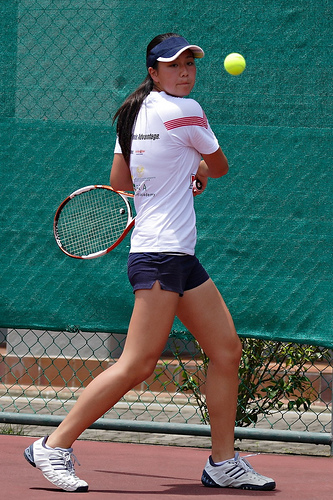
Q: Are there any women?
A: Yes, there is a woman.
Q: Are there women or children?
A: Yes, there is a woman.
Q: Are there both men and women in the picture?
A: No, there is a woman but no men.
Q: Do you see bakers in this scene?
A: No, there are no bakers.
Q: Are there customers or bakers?
A: No, there are no bakers or customers.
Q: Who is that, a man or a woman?
A: That is a woman.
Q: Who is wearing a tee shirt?
A: The woman is wearing a tee shirt.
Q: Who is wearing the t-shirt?
A: The woman is wearing a tee shirt.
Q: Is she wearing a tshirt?
A: Yes, the woman is wearing a tshirt.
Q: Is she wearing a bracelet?
A: No, the woman is wearing a tshirt.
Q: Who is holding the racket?
A: The woman is holding the racket.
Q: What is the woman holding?
A: The woman is holding the racket.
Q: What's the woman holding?
A: The woman is holding the racket.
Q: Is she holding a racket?
A: Yes, the woman is holding a racket.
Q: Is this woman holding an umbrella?
A: No, the woman is holding a racket.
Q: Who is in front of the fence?
A: The woman is in front of the fence.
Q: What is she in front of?
A: The woman is in front of the fence.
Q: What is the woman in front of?
A: The woman is in front of the fence.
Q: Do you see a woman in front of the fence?
A: Yes, there is a woman in front of the fence.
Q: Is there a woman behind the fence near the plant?
A: No, the woman is in front of the fence.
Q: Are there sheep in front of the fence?
A: No, there is a woman in front of the fence.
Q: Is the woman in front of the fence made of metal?
A: Yes, the woman is in front of the fence.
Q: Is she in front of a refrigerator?
A: No, the woman is in front of the fence.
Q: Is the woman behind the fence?
A: No, the woman is in front of the fence.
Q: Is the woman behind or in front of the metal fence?
A: The woman is in front of the fence.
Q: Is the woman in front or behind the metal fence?
A: The woman is in front of the fence.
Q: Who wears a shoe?
A: The woman wears a shoe.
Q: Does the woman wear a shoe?
A: Yes, the woman wears a shoe.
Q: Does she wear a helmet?
A: No, the woman wears a shoe.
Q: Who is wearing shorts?
A: The woman is wearing shorts.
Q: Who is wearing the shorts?
A: The woman is wearing shorts.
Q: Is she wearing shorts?
A: Yes, the woman is wearing shorts.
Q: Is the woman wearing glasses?
A: No, the woman is wearing shorts.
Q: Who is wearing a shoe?
A: The woman is wearing a shoe.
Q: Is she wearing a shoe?
A: Yes, the woman is wearing a shoe.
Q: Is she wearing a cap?
A: No, the woman is wearing a shoe.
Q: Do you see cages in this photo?
A: No, there are no cages.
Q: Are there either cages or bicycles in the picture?
A: No, there are no cages or bicycles.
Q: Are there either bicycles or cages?
A: No, there are no cages or bicycles.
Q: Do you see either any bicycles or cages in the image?
A: No, there are no cages or bicycles.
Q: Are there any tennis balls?
A: Yes, there is a tennis ball.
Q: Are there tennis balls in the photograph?
A: Yes, there is a tennis ball.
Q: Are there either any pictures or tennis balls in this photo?
A: Yes, there is a tennis ball.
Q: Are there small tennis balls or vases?
A: Yes, there is a small tennis ball.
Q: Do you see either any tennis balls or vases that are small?
A: Yes, the tennis ball is small.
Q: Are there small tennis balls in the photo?
A: Yes, there is a small tennis ball.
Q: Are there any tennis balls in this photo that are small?
A: Yes, there is a tennis ball that is small.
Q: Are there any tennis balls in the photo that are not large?
A: Yes, there is a small tennis ball.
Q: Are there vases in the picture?
A: No, there are no vases.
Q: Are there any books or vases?
A: No, there are no vases or books.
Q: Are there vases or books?
A: No, there are no vases or books.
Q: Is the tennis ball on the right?
A: Yes, the tennis ball is on the right of the image.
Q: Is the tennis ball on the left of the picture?
A: No, the tennis ball is on the right of the image.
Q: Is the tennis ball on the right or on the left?
A: The tennis ball is on the right of the image.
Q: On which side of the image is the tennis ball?
A: The tennis ball is on the right of the image.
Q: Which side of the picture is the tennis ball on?
A: The tennis ball is on the right of the image.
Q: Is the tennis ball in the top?
A: Yes, the tennis ball is in the top of the image.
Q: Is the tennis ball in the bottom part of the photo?
A: No, the tennis ball is in the top of the image.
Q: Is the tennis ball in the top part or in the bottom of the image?
A: The tennis ball is in the top of the image.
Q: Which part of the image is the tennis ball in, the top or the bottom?
A: The tennis ball is in the top of the image.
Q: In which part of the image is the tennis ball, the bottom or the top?
A: The tennis ball is in the top of the image.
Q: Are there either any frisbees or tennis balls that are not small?
A: No, there is a tennis ball but it is small.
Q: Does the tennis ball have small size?
A: Yes, the tennis ball is small.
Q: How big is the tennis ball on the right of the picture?
A: The tennis ball is small.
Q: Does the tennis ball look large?
A: No, the tennis ball is small.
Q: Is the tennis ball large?
A: No, the tennis ball is small.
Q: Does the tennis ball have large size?
A: No, the tennis ball is small.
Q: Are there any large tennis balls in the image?
A: No, there is a tennis ball but it is small.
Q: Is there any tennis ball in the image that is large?
A: No, there is a tennis ball but it is small.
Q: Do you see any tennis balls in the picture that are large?
A: No, there is a tennis ball but it is small.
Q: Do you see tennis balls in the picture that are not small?
A: No, there is a tennis ball but it is small.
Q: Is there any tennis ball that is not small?
A: No, there is a tennis ball but it is small.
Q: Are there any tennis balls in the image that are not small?
A: No, there is a tennis ball but it is small.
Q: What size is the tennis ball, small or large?
A: The tennis ball is small.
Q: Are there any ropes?
A: No, there are no ropes.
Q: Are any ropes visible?
A: No, there are no ropes.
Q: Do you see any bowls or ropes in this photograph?
A: No, there are no ropes or bowls.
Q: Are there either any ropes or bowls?
A: No, there are no ropes or bowls.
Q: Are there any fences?
A: Yes, there is a fence.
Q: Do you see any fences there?
A: Yes, there is a fence.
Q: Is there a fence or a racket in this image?
A: Yes, there is a fence.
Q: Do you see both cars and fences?
A: No, there is a fence but no cars.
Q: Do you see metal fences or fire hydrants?
A: Yes, there is a metal fence.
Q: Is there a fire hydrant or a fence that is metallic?
A: Yes, the fence is metallic.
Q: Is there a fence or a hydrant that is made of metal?
A: Yes, the fence is made of metal.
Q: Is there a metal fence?
A: Yes, there is a fence that is made of metal.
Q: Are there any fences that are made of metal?
A: Yes, there is a fence that is made of metal.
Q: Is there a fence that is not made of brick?
A: Yes, there is a fence that is made of metal.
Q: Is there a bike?
A: No, there are no bikes.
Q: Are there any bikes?
A: No, there are no bikes.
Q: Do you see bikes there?
A: No, there are no bikes.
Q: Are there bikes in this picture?
A: No, there are no bikes.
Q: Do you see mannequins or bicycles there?
A: No, there are no bicycles or mannequins.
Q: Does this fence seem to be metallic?
A: Yes, the fence is metallic.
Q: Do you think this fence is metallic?
A: Yes, the fence is metallic.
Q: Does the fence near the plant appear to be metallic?
A: Yes, the fence is metallic.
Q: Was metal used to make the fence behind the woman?
A: Yes, the fence is made of metal.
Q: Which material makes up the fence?
A: The fence is made of metal.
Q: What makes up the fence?
A: The fence is made of metal.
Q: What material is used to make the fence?
A: The fence is made of metal.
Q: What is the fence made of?
A: The fence is made of metal.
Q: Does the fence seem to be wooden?
A: No, the fence is metallic.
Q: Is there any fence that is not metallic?
A: No, there is a fence but it is metallic.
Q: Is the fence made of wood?
A: No, the fence is made of metal.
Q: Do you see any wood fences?
A: No, there is a fence but it is made of metal.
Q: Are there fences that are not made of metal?
A: No, there is a fence but it is made of metal.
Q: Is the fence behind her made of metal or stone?
A: The fence is made of metal.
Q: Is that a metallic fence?
A: Yes, that is a metallic fence.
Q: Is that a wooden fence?
A: No, that is a metallic fence.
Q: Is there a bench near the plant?
A: No, there is a fence near the plant.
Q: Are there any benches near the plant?
A: No, there is a fence near the plant.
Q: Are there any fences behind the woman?
A: Yes, there is a fence behind the woman.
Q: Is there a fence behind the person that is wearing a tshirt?
A: Yes, there is a fence behind the woman.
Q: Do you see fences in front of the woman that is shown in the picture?
A: No, the fence is behind the woman.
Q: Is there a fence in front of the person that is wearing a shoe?
A: No, the fence is behind the woman.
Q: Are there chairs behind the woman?
A: No, there is a fence behind the woman.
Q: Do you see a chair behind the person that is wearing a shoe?
A: No, there is a fence behind the woman.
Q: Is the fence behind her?
A: Yes, the fence is behind the woman.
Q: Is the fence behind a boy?
A: No, the fence is behind the woman.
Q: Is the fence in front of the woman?
A: No, the fence is behind the woman.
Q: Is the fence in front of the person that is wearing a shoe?
A: No, the fence is behind the woman.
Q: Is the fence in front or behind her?
A: The fence is behind the woman.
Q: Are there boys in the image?
A: No, there are no boys.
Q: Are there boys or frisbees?
A: No, there are no boys or frisbees.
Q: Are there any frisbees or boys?
A: No, there are no boys or frisbees.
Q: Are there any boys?
A: No, there are no boys.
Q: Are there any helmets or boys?
A: No, there are no boys or helmets.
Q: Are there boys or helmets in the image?
A: No, there are no boys or helmets.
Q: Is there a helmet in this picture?
A: No, there are no helmets.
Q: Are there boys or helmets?
A: No, there are no helmets or boys.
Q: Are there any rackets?
A: Yes, there is a racket.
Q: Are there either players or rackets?
A: Yes, there is a racket.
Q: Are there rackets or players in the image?
A: Yes, there is a racket.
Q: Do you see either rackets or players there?
A: Yes, there is a racket.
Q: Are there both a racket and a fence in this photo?
A: Yes, there are both a racket and a fence.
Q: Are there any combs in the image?
A: No, there are no combs.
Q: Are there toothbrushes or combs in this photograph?
A: No, there are no combs or toothbrushes.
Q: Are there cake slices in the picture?
A: No, there are no cake slices.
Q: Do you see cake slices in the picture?
A: No, there are no cake slices.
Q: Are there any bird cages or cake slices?
A: No, there are no cake slices or bird cages.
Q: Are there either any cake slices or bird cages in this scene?
A: No, there are no cake slices or bird cages.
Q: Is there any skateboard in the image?
A: No, there are no skateboards.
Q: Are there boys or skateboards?
A: No, there are no skateboards or boys.